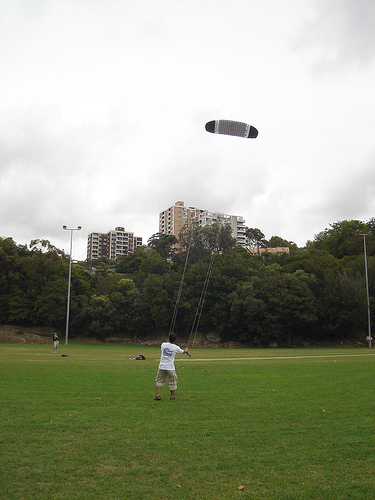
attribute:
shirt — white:
[155, 339, 178, 371]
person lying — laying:
[129, 353, 145, 362]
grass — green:
[3, 345, 374, 497]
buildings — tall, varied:
[88, 191, 272, 263]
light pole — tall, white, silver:
[62, 225, 82, 344]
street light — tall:
[57, 222, 81, 345]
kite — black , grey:
[203, 120, 260, 139]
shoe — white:
[53, 350, 57, 354]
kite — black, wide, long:
[204, 115, 259, 140]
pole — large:
[49, 213, 105, 360]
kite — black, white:
[206, 118, 259, 139]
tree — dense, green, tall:
[4, 236, 372, 344]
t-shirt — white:
[156, 339, 186, 371]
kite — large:
[171, 120, 245, 343]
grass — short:
[83, 406, 165, 451]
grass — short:
[249, 393, 307, 441]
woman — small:
[49, 331, 61, 350]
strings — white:
[178, 152, 206, 341]